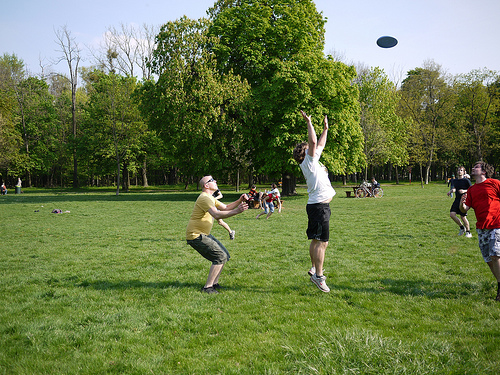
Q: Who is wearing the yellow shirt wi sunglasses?
A: Man in center squatting.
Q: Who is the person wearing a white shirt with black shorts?
A: The man jumping in the air.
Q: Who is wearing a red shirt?
A: Man in the right side of photo.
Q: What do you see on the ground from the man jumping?
A: His shadow.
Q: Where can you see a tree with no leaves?
A: In the background on the left.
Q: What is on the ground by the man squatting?
A: His shadow.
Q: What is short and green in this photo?
A: The grass.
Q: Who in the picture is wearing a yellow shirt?
A: The man squatting.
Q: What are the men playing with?
A: Frisbee.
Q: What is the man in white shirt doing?
A: Jumping.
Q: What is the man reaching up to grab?
A: Frisbee.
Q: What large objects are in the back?
A: Trees.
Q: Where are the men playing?
A: Park.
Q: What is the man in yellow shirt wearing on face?
A: Sunglasses.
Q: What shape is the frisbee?
A: Round.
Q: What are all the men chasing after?
A: Frisbee.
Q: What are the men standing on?
A: Grass.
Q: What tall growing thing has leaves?
A: Tree.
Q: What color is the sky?
A: Pale blue.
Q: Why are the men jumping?
A: They are playing frisbee.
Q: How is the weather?
A: Clear.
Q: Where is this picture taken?
A: A park.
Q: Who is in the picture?
A: Men and women.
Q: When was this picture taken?
A: Daytime.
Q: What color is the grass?
A: Green.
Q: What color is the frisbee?
A: Blue.